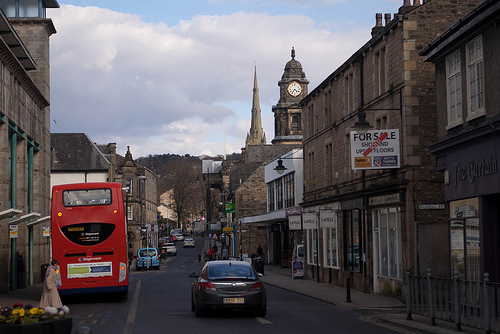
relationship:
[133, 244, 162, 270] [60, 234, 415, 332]
car in street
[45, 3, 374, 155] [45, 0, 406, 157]
clouds in blue sky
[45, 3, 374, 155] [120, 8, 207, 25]
clouds in blue sky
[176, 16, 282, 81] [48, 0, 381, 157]
clouds in sky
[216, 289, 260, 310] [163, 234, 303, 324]
license plate in car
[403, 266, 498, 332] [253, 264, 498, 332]
fence in sidewalk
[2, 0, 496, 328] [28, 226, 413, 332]
buildings in street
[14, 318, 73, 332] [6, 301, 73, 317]
pot in flowesr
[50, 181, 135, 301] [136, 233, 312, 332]
bus on street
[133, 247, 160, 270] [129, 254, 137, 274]
car parked next to curb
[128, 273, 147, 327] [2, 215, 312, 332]
line painted on street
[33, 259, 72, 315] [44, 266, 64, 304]
woman wears coat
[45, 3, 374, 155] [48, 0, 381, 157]
clouds in sky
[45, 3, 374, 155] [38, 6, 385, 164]
clouds in sky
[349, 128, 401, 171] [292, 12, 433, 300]
sign on building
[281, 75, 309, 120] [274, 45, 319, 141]
clock in tower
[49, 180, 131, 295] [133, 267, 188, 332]
bus on street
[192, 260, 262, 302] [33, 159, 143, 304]
car near bus